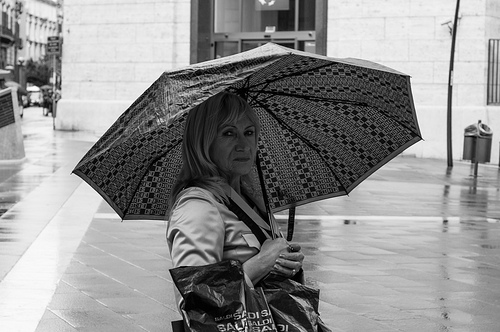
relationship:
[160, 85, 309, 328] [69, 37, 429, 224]
woman under umbrella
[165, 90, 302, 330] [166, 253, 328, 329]
lady carrying shopping bags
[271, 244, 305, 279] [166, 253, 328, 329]
hand holding shopping bags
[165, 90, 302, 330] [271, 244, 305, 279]
lady has hand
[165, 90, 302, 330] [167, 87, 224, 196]
lady has blonde hair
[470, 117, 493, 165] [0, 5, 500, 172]
garbage bin near building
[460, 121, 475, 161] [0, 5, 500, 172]
garbage bin near building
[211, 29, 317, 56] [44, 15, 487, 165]
doors on building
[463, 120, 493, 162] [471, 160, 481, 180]
trash can on pole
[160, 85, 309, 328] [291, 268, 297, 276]
woman wearing ring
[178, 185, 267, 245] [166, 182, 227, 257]
strap on shoulder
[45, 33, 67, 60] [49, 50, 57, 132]
sign on pole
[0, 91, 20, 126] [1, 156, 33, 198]
black sign on cement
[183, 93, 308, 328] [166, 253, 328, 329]
woman holding shopping bags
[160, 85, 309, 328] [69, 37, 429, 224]
woman holding umbrella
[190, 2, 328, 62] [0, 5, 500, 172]
doorway on building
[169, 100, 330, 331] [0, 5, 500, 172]
woman in front of building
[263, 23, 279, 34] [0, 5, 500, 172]
sign in front of building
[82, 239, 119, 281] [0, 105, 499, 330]
pattern on walk way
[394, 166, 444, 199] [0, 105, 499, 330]
pattern on walk way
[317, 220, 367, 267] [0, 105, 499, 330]
pattern on walk way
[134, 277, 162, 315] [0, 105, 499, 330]
pattern on walk way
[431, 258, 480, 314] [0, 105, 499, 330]
pattern on walk way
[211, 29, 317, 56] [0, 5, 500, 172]
doors on building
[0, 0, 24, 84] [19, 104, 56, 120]
building near street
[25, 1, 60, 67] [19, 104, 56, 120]
building near street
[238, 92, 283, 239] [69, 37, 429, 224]
umbrella handle on umbrella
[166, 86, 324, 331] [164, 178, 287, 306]
woman wearing shirt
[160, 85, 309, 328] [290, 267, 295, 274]
woman wearing ring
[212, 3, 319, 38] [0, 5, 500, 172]
window on building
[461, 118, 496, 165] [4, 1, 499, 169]
trash can in background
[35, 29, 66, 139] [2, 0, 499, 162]
signs in distance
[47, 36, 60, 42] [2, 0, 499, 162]
signs in distance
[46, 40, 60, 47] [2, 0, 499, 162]
signs in distance